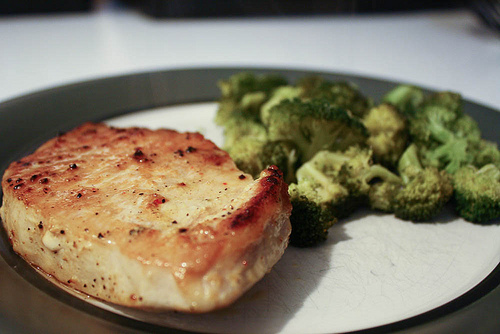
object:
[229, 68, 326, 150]
veggies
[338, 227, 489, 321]
plate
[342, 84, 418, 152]
veggies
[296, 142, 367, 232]
veggies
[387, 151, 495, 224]
veggies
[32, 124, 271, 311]
fish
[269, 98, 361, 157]
broccoli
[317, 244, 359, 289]
marks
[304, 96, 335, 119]
florets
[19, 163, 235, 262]
meat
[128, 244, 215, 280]
moisture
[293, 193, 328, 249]
crown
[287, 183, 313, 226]
floret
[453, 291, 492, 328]
rim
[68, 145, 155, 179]
seasoning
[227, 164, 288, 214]
marks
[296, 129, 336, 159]
stem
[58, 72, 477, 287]
food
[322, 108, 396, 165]
green